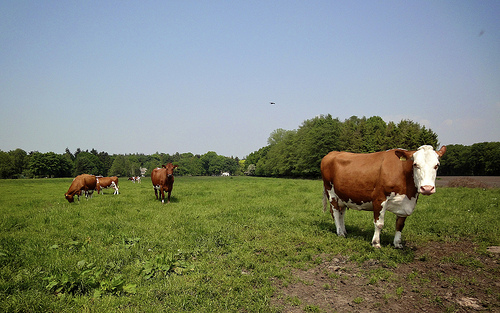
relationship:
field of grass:
[14, 167, 458, 308] [14, 169, 455, 310]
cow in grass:
[49, 170, 104, 205] [57, 208, 117, 251]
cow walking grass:
[141, 157, 187, 204] [51, 224, 233, 277]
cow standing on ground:
[318, 143, 446, 249] [4, 173, 495, 310]